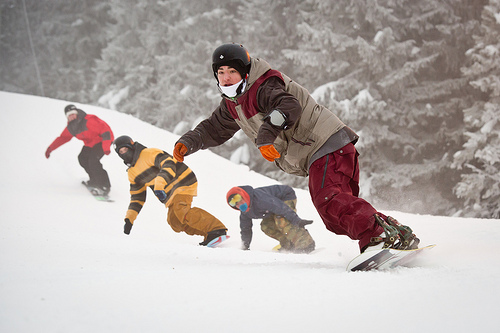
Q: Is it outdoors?
A: Yes, it is outdoors.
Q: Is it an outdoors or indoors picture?
A: It is outdoors.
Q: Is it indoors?
A: No, it is outdoors.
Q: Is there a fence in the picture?
A: No, there are no fences.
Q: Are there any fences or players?
A: No, there are no fences or players.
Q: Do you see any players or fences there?
A: No, there are no fences or players.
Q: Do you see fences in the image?
A: No, there are no fences.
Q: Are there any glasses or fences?
A: No, there are no fences or glasses.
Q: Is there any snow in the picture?
A: Yes, there is snow.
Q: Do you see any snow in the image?
A: Yes, there is snow.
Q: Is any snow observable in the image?
A: Yes, there is snow.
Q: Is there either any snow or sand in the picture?
A: Yes, there is snow.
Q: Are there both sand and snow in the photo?
A: No, there is snow but no sand.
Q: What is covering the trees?
A: The snow is covering the trees.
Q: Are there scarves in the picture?
A: Yes, there is a scarf.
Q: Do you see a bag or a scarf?
A: Yes, there is a scarf.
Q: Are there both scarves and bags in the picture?
A: No, there is a scarf but no bags.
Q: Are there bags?
A: No, there are no bags.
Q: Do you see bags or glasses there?
A: No, there are no bags or glasses.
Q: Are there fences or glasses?
A: No, there are no fences or glasses.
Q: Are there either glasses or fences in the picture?
A: No, there are no fences or glasses.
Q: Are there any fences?
A: No, there are no fences.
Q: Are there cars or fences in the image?
A: No, there are no fences or cars.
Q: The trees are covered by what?
A: The trees are covered by the snow.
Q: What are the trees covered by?
A: The trees are covered by the snow.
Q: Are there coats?
A: Yes, there is a coat.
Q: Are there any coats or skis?
A: Yes, there is a coat.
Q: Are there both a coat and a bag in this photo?
A: No, there is a coat but no bags.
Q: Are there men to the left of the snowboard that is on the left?
A: No, the man is to the right of the snow board.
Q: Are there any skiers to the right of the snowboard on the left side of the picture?
A: No, there is a man to the right of the snow board.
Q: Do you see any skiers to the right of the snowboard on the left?
A: No, there is a man to the right of the snow board.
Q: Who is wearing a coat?
A: The man is wearing a coat.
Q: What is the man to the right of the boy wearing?
A: The man is wearing a coat.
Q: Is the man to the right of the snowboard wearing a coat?
A: Yes, the man is wearing a coat.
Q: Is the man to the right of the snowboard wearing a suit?
A: No, the man is wearing a coat.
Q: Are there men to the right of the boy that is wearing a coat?
A: Yes, there is a man to the right of the boy.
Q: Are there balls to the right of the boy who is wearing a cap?
A: No, there is a man to the right of the boy.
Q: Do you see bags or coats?
A: Yes, there is a coat.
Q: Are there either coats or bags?
A: Yes, there is a coat.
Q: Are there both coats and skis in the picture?
A: No, there is a coat but no skis.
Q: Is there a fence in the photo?
A: No, there are no fences.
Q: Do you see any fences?
A: No, there are no fences.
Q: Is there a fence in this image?
A: No, there are no fences.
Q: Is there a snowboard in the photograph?
A: Yes, there is a snowboard.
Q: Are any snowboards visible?
A: Yes, there is a snowboard.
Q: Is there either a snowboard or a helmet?
A: Yes, there is a snowboard.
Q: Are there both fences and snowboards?
A: No, there is a snowboard but no fences.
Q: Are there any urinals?
A: No, there are no urinals.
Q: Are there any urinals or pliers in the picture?
A: No, there are no urinals or pliers.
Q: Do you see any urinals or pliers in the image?
A: No, there are no urinals or pliers.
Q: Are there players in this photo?
A: No, there are no players.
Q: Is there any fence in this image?
A: No, there are no fences.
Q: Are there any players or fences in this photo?
A: No, there are no fences or players.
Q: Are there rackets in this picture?
A: No, there are no rackets.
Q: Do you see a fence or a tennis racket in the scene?
A: No, there are no rackets or fences.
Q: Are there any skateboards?
A: No, there are no skateboards.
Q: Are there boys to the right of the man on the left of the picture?
A: Yes, there is a boy to the right of the man.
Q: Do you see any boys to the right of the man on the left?
A: Yes, there is a boy to the right of the man.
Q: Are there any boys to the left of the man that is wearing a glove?
A: No, the boy is to the right of the man.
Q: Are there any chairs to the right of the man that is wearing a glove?
A: No, there is a boy to the right of the man.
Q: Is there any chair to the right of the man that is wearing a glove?
A: No, there is a boy to the right of the man.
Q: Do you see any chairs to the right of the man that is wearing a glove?
A: No, there is a boy to the right of the man.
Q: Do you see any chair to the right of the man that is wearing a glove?
A: No, there is a boy to the right of the man.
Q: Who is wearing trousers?
A: The boy is wearing trousers.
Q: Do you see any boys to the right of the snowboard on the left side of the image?
A: Yes, there is a boy to the right of the snowboard.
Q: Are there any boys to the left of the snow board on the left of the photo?
A: No, the boy is to the right of the snowboard.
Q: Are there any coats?
A: Yes, there is a coat.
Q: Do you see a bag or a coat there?
A: Yes, there is a coat.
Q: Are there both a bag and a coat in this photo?
A: No, there is a coat but no bags.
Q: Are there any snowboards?
A: Yes, there is a snowboard.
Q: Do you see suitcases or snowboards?
A: Yes, there is a snowboard.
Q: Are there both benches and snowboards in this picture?
A: No, there is a snowboard but no benches.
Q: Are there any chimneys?
A: No, there are no chimneys.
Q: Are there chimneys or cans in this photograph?
A: No, there are no chimneys or cans.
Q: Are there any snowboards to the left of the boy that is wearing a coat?
A: Yes, there is a snowboard to the left of the boy.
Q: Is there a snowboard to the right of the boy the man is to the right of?
A: No, the snowboard is to the left of the boy.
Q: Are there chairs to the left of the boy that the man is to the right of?
A: No, there is a snowboard to the left of the boy.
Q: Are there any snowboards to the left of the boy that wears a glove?
A: Yes, there is a snowboard to the left of the boy.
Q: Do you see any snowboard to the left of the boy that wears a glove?
A: Yes, there is a snowboard to the left of the boy.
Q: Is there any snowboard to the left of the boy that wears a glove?
A: Yes, there is a snowboard to the left of the boy.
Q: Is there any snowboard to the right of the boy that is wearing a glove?
A: No, the snowboard is to the left of the boy.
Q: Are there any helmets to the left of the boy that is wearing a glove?
A: No, there is a snowboard to the left of the boy.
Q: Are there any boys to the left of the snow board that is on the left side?
A: No, the boy is to the right of the snowboard.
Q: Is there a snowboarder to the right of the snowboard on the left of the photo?
A: No, there is a boy to the right of the snowboard.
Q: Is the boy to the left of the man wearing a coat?
A: Yes, the boy is wearing a coat.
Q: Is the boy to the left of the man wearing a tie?
A: No, the boy is wearing a coat.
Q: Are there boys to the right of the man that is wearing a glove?
A: Yes, there is a boy to the right of the man.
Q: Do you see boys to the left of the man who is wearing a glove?
A: No, the boy is to the right of the man.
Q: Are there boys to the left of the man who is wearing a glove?
A: No, the boy is to the right of the man.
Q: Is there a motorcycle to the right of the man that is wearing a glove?
A: No, there is a boy to the right of the man.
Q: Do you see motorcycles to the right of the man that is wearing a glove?
A: No, there is a boy to the right of the man.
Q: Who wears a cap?
A: The boy wears a cap.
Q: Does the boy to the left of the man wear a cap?
A: Yes, the boy wears a cap.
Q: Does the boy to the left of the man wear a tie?
A: No, the boy wears a cap.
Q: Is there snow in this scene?
A: Yes, there is snow.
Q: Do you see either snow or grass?
A: Yes, there is snow.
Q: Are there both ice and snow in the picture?
A: No, there is snow but no ice.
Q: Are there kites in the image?
A: No, there are no kites.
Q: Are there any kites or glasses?
A: No, there are no kites or glasses.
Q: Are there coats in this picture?
A: Yes, there is a coat.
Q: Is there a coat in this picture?
A: Yes, there is a coat.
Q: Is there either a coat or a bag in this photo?
A: Yes, there is a coat.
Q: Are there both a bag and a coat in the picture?
A: No, there is a coat but no bags.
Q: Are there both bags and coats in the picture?
A: No, there is a coat but no bags.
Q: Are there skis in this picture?
A: No, there are no skis.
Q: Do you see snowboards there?
A: Yes, there is a snowboard.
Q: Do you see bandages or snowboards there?
A: Yes, there is a snowboard.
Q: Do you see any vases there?
A: No, there are no vases.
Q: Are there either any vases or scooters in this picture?
A: No, there are no vases or scooters.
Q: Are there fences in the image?
A: No, there are no fences.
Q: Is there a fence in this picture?
A: No, there are no fences.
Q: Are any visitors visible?
A: No, there are no visitors.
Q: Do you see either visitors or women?
A: No, there are no visitors or women.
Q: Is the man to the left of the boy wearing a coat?
A: Yes, the man is wearing a coat.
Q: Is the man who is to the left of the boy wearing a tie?
A: No, the man is wearing a coat.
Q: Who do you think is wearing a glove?
A: The man is wearing a glove.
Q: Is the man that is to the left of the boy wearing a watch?
A: No, the man is wearing a glove.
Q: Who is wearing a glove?
A: The man is wearing a glove.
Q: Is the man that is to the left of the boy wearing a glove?
A: Yes, the man is wearing a glove.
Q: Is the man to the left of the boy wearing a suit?
A: No, the man is wearing a glove.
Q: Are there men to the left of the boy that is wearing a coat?
A: Yes, there is a man to the left of the boy.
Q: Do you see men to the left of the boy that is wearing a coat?
A: Yes, there is a man to the left of the boy.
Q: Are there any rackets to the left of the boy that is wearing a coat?
A: No, there is a man to the left of the boy.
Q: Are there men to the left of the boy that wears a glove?
A: Yes, there is a man to the left of the boy.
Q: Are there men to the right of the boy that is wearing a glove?
A: No, the man is to the left of the boy.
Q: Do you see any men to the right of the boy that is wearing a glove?
A: No, the man is to the left of the boy.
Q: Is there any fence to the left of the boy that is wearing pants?
A: No, there is a man to the left of the boy.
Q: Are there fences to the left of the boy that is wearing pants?
A: No, there is a man to the left of the boy.